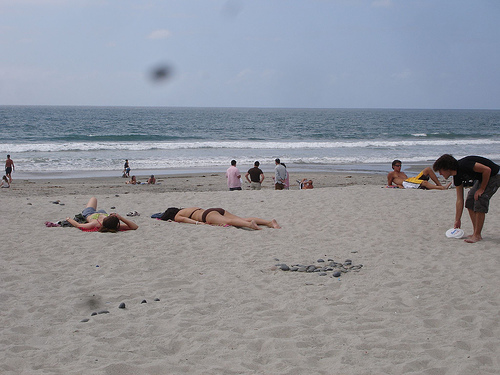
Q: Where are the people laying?
A: On beach.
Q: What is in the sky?
A: Cloud.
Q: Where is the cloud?
A: In sky.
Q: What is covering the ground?
A: Sand.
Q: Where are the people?
A: At the beach.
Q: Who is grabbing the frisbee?
A: The man with a black shirt.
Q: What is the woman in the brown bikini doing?
A: Sunbathing.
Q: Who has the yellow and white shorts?
A: The man.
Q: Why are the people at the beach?
A: Relaxation.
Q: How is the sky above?
A: Clear.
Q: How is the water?
A: Calm.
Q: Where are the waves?
A: In the ocean.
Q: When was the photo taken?
A: During the daytime.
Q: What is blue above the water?
A: The sky.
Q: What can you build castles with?
A: Sand.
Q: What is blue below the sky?
A: Water.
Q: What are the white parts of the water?
A: Waves.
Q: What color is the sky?
A: Blue.